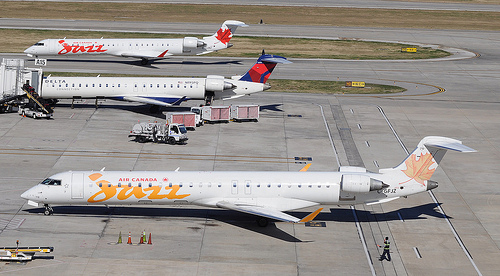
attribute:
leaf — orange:
[396, 143, 440, 185]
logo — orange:
[93, 180, 188, 202]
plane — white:
[24, 133, 486, 244]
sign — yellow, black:
[351, 79, 362, 88]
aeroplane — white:
[20, 137, 463, 233]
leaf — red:
[216, 25, 233, 45]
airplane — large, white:
[45, 131, 440, 231]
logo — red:
[58, 40, 106, 55]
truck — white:
[132, 120, 187, 148]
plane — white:
[22, 17, 241, 65]